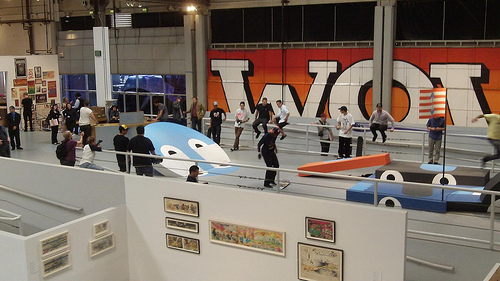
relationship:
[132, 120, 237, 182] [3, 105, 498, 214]
object attached to floor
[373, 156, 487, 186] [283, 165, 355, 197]
black block on floor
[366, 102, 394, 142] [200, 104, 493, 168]
boys sitting on railing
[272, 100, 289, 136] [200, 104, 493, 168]
boys sitting on railing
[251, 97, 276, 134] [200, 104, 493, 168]
boys sitting on railing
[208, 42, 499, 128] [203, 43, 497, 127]
wall has coloring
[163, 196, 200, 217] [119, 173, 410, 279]
picture on wall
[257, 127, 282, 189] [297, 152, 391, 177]
man skateboarding near orange ramp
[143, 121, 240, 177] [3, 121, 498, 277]
object on floor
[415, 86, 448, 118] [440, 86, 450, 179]
flag on pole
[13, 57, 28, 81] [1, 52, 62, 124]
picture on wall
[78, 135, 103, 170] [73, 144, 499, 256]
people looking over railing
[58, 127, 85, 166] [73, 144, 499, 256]
people looking over railing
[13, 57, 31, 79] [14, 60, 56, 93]
pictures on wall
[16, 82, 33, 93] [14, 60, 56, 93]
pictures on wall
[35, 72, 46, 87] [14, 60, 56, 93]
pictures on wall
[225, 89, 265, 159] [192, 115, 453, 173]
person leaning railing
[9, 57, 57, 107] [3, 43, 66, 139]
signs on wall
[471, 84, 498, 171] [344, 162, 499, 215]
man jumping objects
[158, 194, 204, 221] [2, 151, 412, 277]
picture on wall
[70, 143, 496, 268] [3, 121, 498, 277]
railing on floor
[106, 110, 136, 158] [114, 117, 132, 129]
man wearing hat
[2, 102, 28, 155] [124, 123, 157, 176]
man in suit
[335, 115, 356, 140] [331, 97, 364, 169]
shirt on person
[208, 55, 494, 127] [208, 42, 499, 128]
lettering on wall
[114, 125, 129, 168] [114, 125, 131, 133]
person wearing hat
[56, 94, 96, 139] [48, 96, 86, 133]
man wearing shirt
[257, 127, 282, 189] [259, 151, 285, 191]
man wearing black pants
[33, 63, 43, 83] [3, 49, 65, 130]
picture on wall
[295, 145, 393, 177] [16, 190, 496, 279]
block on floor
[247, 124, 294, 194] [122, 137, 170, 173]
man in suit